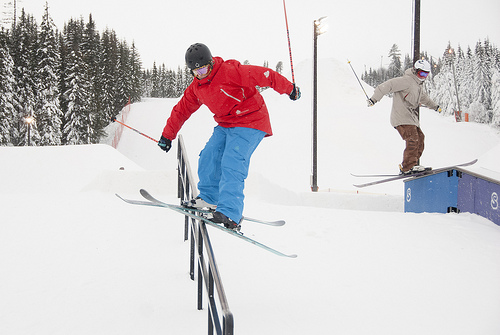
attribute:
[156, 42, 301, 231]
person — skiing, jumping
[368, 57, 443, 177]
person — skiing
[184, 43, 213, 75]
helmet — black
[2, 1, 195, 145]
tree — here, covered, tall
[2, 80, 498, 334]
snow — white, here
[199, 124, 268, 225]
pants — blue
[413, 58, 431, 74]
helmet — white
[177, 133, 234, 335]
railing — metal, black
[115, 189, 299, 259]
skis — silver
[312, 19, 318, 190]
pole — black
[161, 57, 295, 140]
jacket — red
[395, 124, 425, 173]
trouser — brown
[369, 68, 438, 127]
jacket — gray, grey